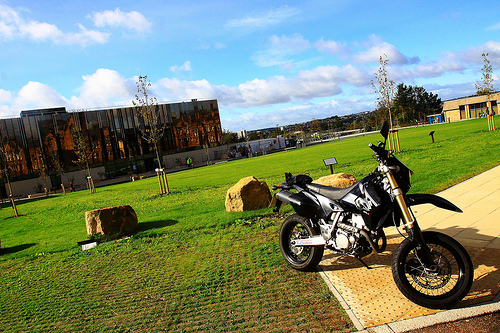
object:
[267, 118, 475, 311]
motorcycle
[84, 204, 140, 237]
rock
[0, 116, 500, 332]
grass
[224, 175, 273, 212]
left rock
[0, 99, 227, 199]
building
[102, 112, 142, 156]
window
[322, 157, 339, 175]
display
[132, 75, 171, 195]
thin tree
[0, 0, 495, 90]
sky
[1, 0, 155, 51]
clouds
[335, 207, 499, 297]
sidewalk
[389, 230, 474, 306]
tire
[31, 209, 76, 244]
patch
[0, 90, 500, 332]
city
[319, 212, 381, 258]
motor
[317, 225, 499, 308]
shadow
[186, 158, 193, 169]
person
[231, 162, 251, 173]
green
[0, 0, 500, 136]
background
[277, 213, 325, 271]
wheel